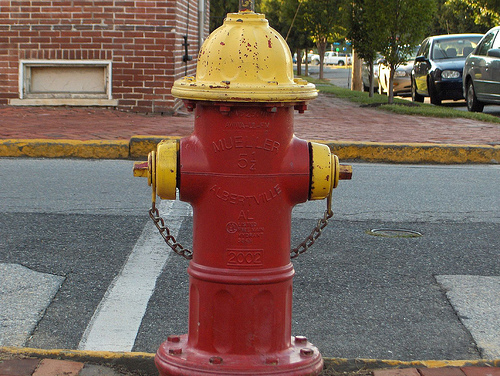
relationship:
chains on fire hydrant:
[138, 189, 334, 272] [123, 0, 373, 373]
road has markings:
[25, 137, 468, 341] [95, 148, 185, 372]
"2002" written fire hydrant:
[225, 246, 273, 267] [135, 10, 354, 369]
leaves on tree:
[375, 9, 383, 16] [346, 6, 435, 105]